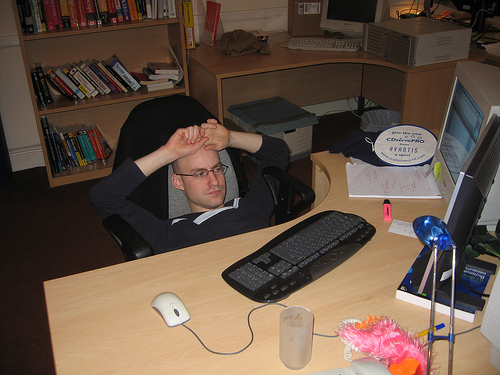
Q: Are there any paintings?
A: No, there are no paintings.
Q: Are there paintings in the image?
A: No, there are no paintings.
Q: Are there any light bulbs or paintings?
A: No, there are no paintings or light bulbs.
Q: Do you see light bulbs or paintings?
A: No, there are no paintings or light bulbs.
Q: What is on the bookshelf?
A: The books are on the bookshelf.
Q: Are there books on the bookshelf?
A: Yes, there are books on the bookshelf.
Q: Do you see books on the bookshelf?
A: Yes, there are books on the bookshelf.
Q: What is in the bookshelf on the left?
A: The books are in the bookshelf.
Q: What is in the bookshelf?
A: The books are in the bookshelf.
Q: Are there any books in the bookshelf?
A: Yes, there are books in the bookshelf.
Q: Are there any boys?
A: No, there are no boys.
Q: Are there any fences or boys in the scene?
A: No, there are no boys or fences.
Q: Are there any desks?
A: Yes, there is a desk.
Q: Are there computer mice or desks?
A: Yes, there is a desk.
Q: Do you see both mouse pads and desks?
A: No, there is a desk but no mouse pads.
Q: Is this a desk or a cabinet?
A: This is a desk.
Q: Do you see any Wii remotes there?
A: No, there are no Wii remotes.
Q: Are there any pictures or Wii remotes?
A: No, there are no Wii remotes or pictures.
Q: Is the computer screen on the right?
A: Yes, the screen is on the right of the image.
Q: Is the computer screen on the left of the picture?
A: No, the screen is on the right of the image.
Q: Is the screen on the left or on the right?
A: The screen is on the right of the image.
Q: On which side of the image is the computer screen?
A: The screen is on the right of the image.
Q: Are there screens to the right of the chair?
A: Yes, there is a screen to the right of the chair.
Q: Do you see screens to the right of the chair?
A: Yes, there is a screen to the right of the chair.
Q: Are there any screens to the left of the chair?
A: No, the screen is to the right of the chair.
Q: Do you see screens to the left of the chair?
A: No, the screen is to the right of the chair.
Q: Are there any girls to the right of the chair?
A: No, there is a screen to the right of the chair.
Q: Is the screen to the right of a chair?
A: Yes, the screen is to the right of a chair.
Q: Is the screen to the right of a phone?
A: No, the screen is to the right of a chair.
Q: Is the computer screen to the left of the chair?
A: No, the screen is to the right of the chair.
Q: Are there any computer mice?
A: Yes, there is a computer mouse.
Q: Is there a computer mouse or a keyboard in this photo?
A: Yes, there is a computer mouse.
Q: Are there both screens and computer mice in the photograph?
A: Yes, there are both a computer mouse and a screen.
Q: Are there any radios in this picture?
A: No, there are no radios.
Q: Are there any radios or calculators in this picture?
A: No, there are no radios or calculators.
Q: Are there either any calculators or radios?
A: No, there are no radios or calculators.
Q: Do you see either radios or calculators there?
A: No, there are no radios or calculators.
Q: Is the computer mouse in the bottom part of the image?
A: Yes, the computer mouse is in the bottom of the image.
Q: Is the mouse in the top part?
A: No, the mouse is in the bottom of the image.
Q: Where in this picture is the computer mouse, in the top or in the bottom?
A: The computer mouse is in the bottom of the image.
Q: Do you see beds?
A: No, there are no beds.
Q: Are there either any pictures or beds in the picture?
A: No, there are no beds or pictures.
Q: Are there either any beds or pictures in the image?
A: No, there are no beds or pictures.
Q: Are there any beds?
A: No, there are no beds.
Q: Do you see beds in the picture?
A: No, there are no beds.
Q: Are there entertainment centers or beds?
A: No, there are no beds or entertainment centers.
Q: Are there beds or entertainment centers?
A: No, there are no beds or entertainment centers.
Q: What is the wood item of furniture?
A: The piece of furniture is a bookshelf.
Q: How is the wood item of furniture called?
A: The piece of furniture is a bookshelf.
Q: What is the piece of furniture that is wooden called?
A: The piece of furniture is a bookshelf.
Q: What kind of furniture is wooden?
A: The furniture is a bookshelf.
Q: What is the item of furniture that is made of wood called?
A: The piece of furniture is a bookshelf.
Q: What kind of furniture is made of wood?
A: The furniture is a bookshelf.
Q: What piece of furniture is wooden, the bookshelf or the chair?
A: The bookshelf is wooden.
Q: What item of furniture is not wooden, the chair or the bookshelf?
A: The chair is not wooden.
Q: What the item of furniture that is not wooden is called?
A: The piece of furniture is a chair.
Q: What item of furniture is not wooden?
A: The piece of furniture is a chair.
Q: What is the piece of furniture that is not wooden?
A: The piece of furniture is a chair.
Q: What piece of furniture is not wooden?
A: The piece of furniture is a chair.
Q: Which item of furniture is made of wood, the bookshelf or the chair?
A: The bookshelf is made of wood.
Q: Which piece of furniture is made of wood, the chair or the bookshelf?
A: The bookshelf is made of wood.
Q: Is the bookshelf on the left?
A: Yes, the bookshelf is on the left of the image.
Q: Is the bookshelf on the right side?
A: No, the bookshelf is on the left of the image.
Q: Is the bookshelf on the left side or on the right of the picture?
A: The bookshelf is on the left of the image.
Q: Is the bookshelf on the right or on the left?
A: The bookshelf is on the left of the image.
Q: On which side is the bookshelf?
A: The bookshelf is on the left of the image.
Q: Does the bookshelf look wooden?
A: Yes, the bookshelf is wooden.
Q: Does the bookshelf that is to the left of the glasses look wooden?
A: Yes, the bookshelf is wooden.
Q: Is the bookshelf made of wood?
A: Yes, the bookshelf is made of wood.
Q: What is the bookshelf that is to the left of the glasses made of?
A: The bookshelf is made of wood.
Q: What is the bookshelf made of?
A: The bookshelf is made of wood.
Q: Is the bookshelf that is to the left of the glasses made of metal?
A: No, the bookshelf is made of wood.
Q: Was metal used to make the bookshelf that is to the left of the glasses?
A: No, the bookshelf is made of wood.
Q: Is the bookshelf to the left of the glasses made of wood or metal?
A: The bookshelf is made of wood.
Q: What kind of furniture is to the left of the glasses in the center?
A: The piece of furniture is a bookshelf.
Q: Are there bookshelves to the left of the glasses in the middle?
A: Yes, there is a bookshelf to the left of the glasses.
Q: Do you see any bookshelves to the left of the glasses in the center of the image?
A: Yes, there is a bookshelf to the left of the glasses.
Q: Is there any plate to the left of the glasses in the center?
A: No, there is a bookshelf to the left of the glasses.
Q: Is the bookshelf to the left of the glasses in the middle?
A: Yes, the bookshelf is to the left of the glasses.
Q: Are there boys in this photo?
A: No, there are no boys.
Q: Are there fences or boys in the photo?
A: No, there are no boys or fences.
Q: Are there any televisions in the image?
A: Yes, there is a television.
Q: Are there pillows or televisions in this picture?
A: Yes, there is a television.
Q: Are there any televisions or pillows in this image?
A: Yes, there is a television.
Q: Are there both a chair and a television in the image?
A: Yes, there are both a television and a chair.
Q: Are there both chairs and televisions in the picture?
A: Yes, there are both a television and a chair.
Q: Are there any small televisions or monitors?
A: Yes, there is a small television.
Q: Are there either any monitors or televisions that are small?
A: Yes, the television is small.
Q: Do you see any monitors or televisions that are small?
A: Yes, the television is small.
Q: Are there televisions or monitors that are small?
A: Yes, the television is small.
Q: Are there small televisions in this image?
A: Yes, there is a small television.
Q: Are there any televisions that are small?
A: Yes, there is a television that is small.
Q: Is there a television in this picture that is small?
A: Yes, there is a television that is small.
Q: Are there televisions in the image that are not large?
A: Yes, there is a small television.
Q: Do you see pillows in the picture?
A: No, there are no pillows.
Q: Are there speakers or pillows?
A: No, there are no pillows or speakers.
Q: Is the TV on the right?
A: Yes, the TV is on the right of the image.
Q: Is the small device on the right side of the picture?
A: Yes, the TV is on the right of the image.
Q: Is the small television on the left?
A: No, the television is on the right of the image.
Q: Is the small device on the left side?
A: No, the television is on the right of the image.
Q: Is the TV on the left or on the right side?
A: The TV is on the right of the image.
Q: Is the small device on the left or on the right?
A: The TV is on the right of the image.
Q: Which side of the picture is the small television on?
A: The TV is on the right of the image.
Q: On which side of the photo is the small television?
A: The TV is on the right of the image.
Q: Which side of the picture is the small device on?
A: The TV is on the right of the image.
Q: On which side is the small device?
A: The TV is on the right of the image.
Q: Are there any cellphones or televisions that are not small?
A: No, there is a television but it is small.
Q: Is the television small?
A: Yes, the television is small.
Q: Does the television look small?
A: Yes, the television is small.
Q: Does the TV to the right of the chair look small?
A: Yes, the television is small.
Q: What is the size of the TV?
A: The TV is small.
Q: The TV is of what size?
A: The TV is small.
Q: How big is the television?
A: The television is small.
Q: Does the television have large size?
A: No, the television is small.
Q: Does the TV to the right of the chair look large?
A: No, the TV is small.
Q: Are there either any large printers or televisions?
A: No, there is a television but it is small.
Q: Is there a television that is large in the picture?
A: No, there is a television but it is small.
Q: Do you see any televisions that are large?
A: No, there is a television but it is small.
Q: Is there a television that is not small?
A: No, there is a television but it is small.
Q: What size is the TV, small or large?
A: The TV is small.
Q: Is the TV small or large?
A: The TV is small.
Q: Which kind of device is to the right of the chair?
A: The device is a television.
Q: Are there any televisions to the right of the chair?
A: Yes, there is a television to the right of the chair.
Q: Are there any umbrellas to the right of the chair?
A: No, there is a television to the right of the chair.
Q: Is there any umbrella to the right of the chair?
A: No, there is a television to the right of the chair.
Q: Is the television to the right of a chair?
A: Yes, the television is to the right of a chair.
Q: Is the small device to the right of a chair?
A: Yes, the television is to the right of a chair.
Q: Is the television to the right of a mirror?
A: No, the television is to the right of a chair.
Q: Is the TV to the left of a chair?
A: No, the TV is to the right of a chair.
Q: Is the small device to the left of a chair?
A: No, the TV is to the right of a chair.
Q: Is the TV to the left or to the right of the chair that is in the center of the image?
A: The TV is to the right of the chair.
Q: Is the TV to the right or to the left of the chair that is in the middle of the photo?
A: The TV is to the right of the chair.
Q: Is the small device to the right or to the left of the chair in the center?
A: The TV is to the right of the chair.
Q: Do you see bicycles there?
A: No, there are no bicycles.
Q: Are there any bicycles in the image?
A: No, there are no bicycles.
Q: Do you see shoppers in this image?
A: No, there are no shoppers.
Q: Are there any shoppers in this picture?
A: No, there are no shoppers.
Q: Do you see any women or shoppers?
A: No, there are no shoppers or women.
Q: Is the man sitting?
A: Yes, the man is sitting.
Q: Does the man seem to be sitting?
A: Yes, the man is sitting.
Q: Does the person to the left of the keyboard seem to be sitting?
A: Yes, the man is sitting.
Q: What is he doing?
A: The man is sitting.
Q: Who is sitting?
A: The man is sitting.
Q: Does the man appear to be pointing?
A: No, the man is sitting.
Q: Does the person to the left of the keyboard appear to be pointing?
A: No, the man is sitting.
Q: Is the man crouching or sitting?
A: The man is sitting.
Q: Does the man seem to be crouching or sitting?
A: The man is sitting.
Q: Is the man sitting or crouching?
A: The man is sitting.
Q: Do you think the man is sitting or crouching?
A: The man is sitting.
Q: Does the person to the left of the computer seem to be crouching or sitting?
A: The man is sitting.